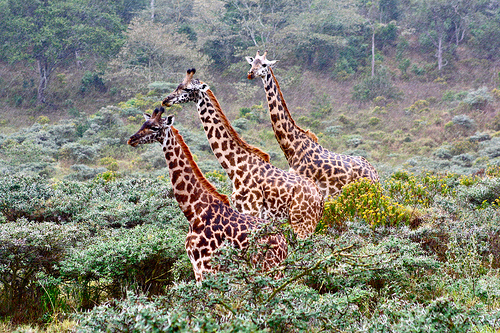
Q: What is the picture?
A: Giraffes.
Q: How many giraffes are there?
A: Three.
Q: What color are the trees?
A: Green.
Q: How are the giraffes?
A: Standing.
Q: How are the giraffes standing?
A: In a row.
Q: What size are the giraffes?
A: Big and tall.